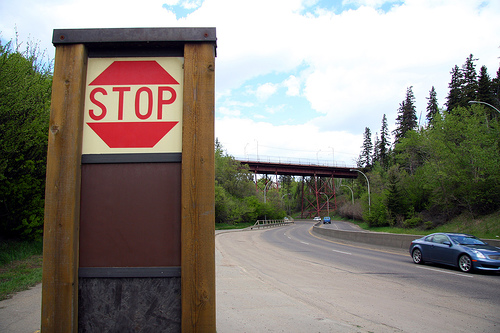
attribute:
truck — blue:
[320, 212, 331, 223]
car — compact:
[319, 212, 334, 232]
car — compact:
[304, 210, 321, 234]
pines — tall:
[356, 56, 498, 242]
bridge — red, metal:
[230, 158, 370, 218]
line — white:
[335, 240, 358, 255]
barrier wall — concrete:
[310, 215, 499, 265]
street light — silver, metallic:
[346, 164, 376, 219]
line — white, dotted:
[327, 245, 354, 257]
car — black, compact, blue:
[407, 226, 497, 275]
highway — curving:
[258, 214, 497, 327]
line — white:
[411, 260, 474, 280]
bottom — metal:
[70, 255, 188, 331]